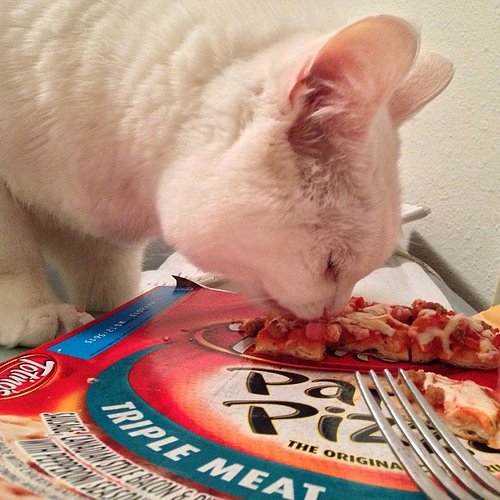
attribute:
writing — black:
[231, 360, 496, 457]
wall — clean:
[378, 1, 495, 311]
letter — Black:
[227, 382, 290, 447]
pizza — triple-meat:
[390, 367, 499, 444]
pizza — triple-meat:
[238, 293, 498, 369]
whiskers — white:
[207, 292, 296, 327]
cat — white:
[4, 7, 468, 322]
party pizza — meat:
[165, 200, 470, 373]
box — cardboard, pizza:
[0, 201, 497, 499]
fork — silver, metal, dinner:
[354, 367, 497, 498]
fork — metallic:
[352, 345, 496, 497]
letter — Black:
[221, 395, 318, 434]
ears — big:
[281, 13, 454, 155]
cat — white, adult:
[1, 2, 455, 349]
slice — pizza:
[251, 293, 452, 392]